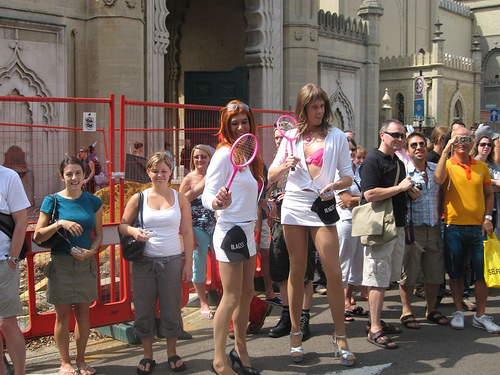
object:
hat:
[471, 123, 500, 142]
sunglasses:
[224, 104, 253, 113]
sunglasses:
[383, 132, 405, 138]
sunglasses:
[409, 140, 427, 149]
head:
[215, 96, 252, 148]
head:
[376, 116, 407, 154]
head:
[403, 129, 429, 161]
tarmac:
[0, 282, 498, 374]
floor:
[2, 284, 498, 375]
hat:
[218, 224, 257, 264]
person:
[268, 82, 359, 361]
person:
[109, 145, 198, 374]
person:
[29, 156, 102, 374]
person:
[352, 116, 421, 344]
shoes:
[330, 338, 358, 366]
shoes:
[363, 329, 398, 350]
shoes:
[134, 357, 157, 374]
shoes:
[49, 359, 77, 373]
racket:
[217, 131, 259, 210]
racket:
[274, 113, 300, 173]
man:
[431, 125, 499, 334]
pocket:
[219, 220, 237, 230]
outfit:
[197, 139, 263, 262]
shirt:
[356, 152, 409, 224]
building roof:
[312, 7, 373, 44]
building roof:
[431, 0, 478, 21]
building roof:
[381, 50, 483, 70]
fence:
[1, 92, 310, 343]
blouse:
[39, 191, 103, 255]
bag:
[482, 230, 500, 289]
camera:
[55, 220, 84, 257]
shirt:
[444, 156, 494, 226]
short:
[126, 253, 190, 340]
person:
[200, 98, 265, 373]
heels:
[227, 348, 262, 375]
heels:
[209, 361, 240, 373]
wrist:
[50, 216, 67, 230]